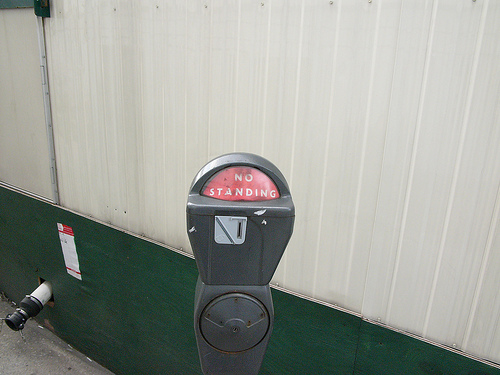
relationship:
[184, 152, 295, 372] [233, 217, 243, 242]
parking meter with coin slot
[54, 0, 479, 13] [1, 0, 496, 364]
screws securing siding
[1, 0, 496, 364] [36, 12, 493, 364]
siding to building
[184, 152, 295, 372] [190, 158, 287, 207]
parking meter with red sign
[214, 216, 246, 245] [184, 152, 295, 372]
coin slot on parking meter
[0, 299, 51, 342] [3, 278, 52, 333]
black cap on hose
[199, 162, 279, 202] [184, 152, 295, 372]
red sign on parking meter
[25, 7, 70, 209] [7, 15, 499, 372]
pipe on wall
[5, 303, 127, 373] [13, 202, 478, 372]
concrete on green board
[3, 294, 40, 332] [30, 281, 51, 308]
end on pipe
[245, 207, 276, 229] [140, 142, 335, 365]
marks on meter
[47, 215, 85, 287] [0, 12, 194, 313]
sticker on wall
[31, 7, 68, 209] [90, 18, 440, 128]
pipe on wall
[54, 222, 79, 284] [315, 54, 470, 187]
sign on wall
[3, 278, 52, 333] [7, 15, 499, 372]
hose coming out of wall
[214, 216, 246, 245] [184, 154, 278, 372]
coin slot in meter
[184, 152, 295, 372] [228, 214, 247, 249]
parking meter with coin slot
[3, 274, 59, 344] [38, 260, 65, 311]
pipe coming out of hole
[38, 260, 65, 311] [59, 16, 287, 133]
hole in outside wall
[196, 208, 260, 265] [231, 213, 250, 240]
panel for coin slot